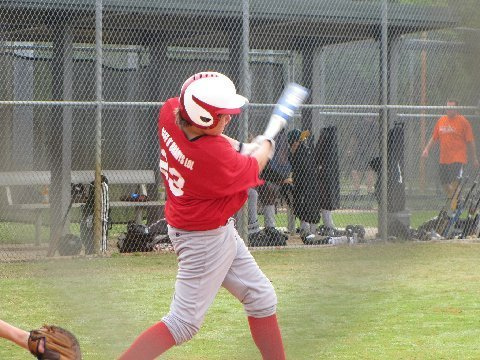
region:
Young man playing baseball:
[120, 41, 353, 357]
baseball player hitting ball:
[120, 36, 324, 354]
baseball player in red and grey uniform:
[111, 45, 337, 354]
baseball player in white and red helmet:
[100, 42, 280, 358]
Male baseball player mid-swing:
[72, 29, 357, 349]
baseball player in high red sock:
[65, 47, 346, 359]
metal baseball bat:
[222, 51, 331, 198]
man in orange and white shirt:
[411, 75, 472, 214]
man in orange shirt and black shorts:
[405, 84, 472, 223]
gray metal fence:
[311, 29, 455, 246]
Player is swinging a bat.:
[245, 69, 312, 166]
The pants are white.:
[175, 242, 265, 314]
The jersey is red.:
[153, 111, 245, 222]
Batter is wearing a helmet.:
[171, 65, 249, 140]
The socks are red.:
[131, 320, 181, 357]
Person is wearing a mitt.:
[14, 322, 80, 359]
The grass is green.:
[339, 268, 440, 344]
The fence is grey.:
[15, 45, 89, 210]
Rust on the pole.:
[85, 167, 120, 256]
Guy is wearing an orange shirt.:
[424, 110, 476, 168]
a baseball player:
[99, 66, 322, 356]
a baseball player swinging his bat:
[93, 47, 315, 352]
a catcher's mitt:
[11, 313, 85, 356]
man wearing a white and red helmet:
[164, 58, 248, 140]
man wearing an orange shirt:
[421, 88, 478, 160]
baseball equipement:
[291, 170, 476, 249]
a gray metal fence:
[5, 73, 96, 245]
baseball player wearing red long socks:
[112, 306, 298, 358]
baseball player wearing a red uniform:
[140, 100, 277, 220]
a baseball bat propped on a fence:
[44, 174, 85, 263]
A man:
[418, 92, 476, 234]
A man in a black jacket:
[281, 124, 330, 245]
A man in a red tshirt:
[108, 63, 300, 355]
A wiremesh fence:
[0, 0, 476, 248]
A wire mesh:
[0, 0, 475, 235]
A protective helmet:
[173, 63, 247, 129]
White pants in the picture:
[162, 220, 275, 340]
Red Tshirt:
[151, 99, 264, 234]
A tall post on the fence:
[91, 1, 107, 258]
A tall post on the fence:
[370, 35, 399, 246]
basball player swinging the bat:
[116, 66, 309, 358]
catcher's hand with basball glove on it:
[23, 320, 86, 358]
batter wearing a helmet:
[170, 69, 249, 141]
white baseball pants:
[163, 216, 281, 347]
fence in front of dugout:
[3, 17, 479, 259]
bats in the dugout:
[429, 159, 478, 242]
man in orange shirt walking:
[419, 94, 478, 218]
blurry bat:
[254, 75, 308, 168]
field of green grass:
[0, 251, 477, 357]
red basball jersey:
[154, 93, 268, 235]